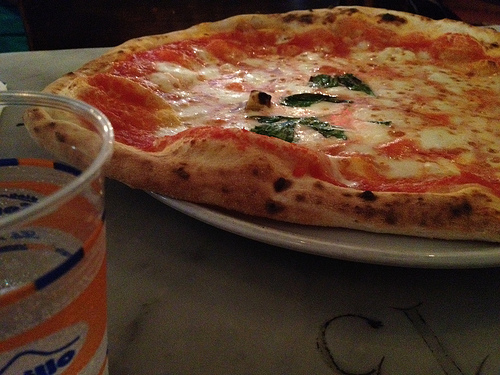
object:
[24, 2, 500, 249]
pizza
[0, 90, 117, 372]
cup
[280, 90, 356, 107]
basil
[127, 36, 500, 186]
cheese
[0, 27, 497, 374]
table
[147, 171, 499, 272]
plate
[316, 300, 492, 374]
"cl"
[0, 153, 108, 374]
soda